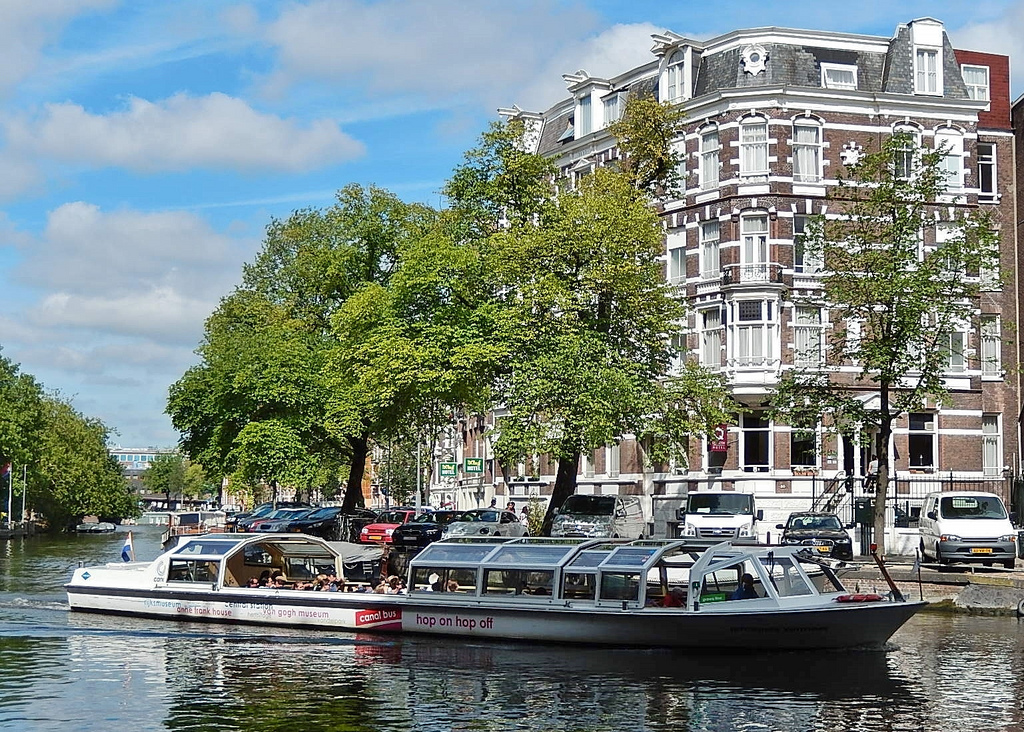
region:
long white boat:
[90, 490, 903, 686]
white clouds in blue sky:
[58, 250, 113, 296]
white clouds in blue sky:
[105, 356, 169, 399]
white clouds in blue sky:
[90, 104, 154, 150]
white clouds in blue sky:
[49, 40, 139, 107]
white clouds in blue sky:
[207, 124, 245, 164]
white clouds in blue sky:
[198, 69, 256, 118]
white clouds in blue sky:
[295, 25, 347, 71]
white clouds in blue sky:
[351, 51, 403, 118]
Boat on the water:
[378, 492, 980, 669]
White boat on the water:
[58, 523, 428, 657]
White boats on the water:
[61, 520, 420, 653]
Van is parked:
[914, 478, 1022, 576]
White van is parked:
[908, 473, 1022, 578]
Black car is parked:
[763, 497, 863, 564]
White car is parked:
[435, 494, 534, 546]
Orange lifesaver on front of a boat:
[817, 576, 897, 615]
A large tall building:
[470, 22, 1020, 601]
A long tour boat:
[91, 513, 918, 676]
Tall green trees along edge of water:
[193, 208, 699, 481]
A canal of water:
[41, 623, 449, 726]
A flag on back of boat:
[111, 522, 150, 562]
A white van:
[917, 471, 1022, 574]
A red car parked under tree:
[353, 497, 436, 548]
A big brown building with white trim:
[698, 108, 820, 517]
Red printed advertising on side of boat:
[328, 591, 521, 653]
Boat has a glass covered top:
[410, 530, 875, 603]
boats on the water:
[23, 515, 932, 692]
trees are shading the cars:
[171, 180, 722, 548]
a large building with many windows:
[496, 31, 1016, 531]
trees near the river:
[1, 363, 145, 551]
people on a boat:
[247, 557, 416, 593]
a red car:
[348, 503, 409, 542]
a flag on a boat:
[115, 528, 141, 567]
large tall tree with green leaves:
[465, 90, 748, 540]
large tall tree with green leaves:
[756, 126, 1012, 554]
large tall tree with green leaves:
[167, 175, 480, 521]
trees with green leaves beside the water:
[3, 355, 143, 533]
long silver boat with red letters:
[398, 537, 929, 652]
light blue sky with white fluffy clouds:
[0, 2, 1016, 451]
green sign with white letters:
[437, 457, 457, 480]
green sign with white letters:
[461, 453, 487, 473]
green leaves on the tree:
[567, 192, 610, 268]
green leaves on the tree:
[573, 391, 643, 464]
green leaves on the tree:
[605, 417, 675, 466]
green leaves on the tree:
[512, 373, 567, 446]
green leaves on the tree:
[468, 373, 494, 399]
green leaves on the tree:
[438, 279, 528, 360]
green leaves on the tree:
[362, 300, 429, 376]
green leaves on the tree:
[313, 341, 386, 425]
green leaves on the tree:
[257, 335, 283, 373]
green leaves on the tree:
[175, 391, 256, 467]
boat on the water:
[50, 470, 992, 667]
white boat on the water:
[50, 432, 970, 730]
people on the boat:
[109, 456, 1005, 697]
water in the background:
[81, 568, 995, 706]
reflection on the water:
[34, 527, 880, 721]